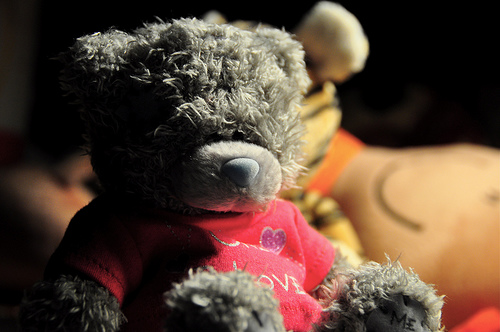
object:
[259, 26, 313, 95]
ear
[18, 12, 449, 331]
bear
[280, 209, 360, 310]
arm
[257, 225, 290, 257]
heart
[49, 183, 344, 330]
shirt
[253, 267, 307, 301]
ove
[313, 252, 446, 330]
foot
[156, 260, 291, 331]
foot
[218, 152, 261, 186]
nose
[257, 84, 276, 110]
eyes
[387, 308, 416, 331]
me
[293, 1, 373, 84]
ear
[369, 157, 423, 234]
smile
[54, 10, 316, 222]
head